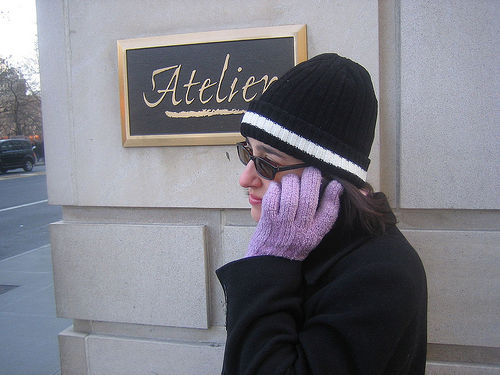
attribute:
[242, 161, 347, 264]
glove — purple, woman's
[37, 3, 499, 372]
building — stone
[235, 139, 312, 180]
sunglasses — black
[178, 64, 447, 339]
face — woman's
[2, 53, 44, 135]
trees — bare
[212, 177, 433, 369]
coat — black, trench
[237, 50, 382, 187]
hat — black, white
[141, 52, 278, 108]
letters — gold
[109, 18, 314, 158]
sign — black, gold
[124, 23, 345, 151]
sign — black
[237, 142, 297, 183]
sunglasses — black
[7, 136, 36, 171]
vehicle — black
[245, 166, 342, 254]
glove — purple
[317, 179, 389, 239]
hair — brown, short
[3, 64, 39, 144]
trees — dead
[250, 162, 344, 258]
glove — purple